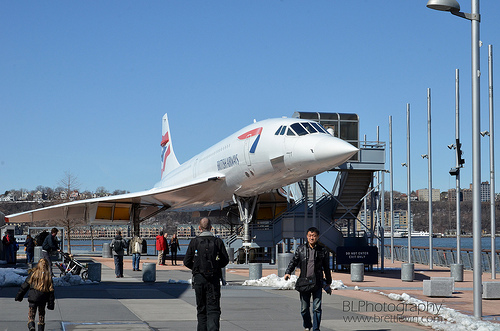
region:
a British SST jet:
[8, 93, 363, 234]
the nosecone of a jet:
[333, 135, 360, 162]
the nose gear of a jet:
[228, 202, 264, 272]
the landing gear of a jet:
[224, 190, 271, 258]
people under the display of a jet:
[13, 114, 358, 319]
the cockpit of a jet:
[278, 120, 329, 137]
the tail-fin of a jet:
[145, 108, 181, 163]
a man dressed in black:
[176, 213, 238, 327]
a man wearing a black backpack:
[174, 210, 236, 330]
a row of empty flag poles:
[366, 96, 499, 316]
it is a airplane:
[0, 108, 357, 221]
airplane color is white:
[0, 93, 365, 223]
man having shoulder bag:
[287, 271, 329, 293]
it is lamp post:
[427, 1, 498, 326]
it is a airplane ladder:
[327, 160, 388, 226]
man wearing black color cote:
[185, 212, 227, 327]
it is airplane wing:
[4, 182, 211, 233]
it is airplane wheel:
[240, 236, 270, 263]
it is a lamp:
[424, 1, 473, 28]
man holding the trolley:
[43, 229, 110, 279]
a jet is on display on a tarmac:
[3, 98, 359, 283]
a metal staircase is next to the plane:
[285, 107, 387, 272]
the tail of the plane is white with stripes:
[146, 107, 191, 180]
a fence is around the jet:
[3, 224, 499, 292]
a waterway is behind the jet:
[16, 226, 499, 301]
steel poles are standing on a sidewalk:
[365, 48, 498, 325]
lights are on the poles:
[380, 121, 493, 171]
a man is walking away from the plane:
[278, 221, 340, 329]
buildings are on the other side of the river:
[1, 173, 496, 247]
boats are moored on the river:
[367, 224, 448, 242]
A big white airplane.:
[5, 112, 357, 263]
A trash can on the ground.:
[85, 260, 101, 283]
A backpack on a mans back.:
[112, 237, 122, 251]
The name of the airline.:
[212, 154, 238, 170]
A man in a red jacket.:
[153, 231, 165, 266]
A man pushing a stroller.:
[60, 251, 90, 281]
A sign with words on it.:
[337, 244, 379, 264]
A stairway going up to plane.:
[292, 172, 314, 214]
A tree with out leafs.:
[57, 168, 78, 196]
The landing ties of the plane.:
[237, 247, 254, 265]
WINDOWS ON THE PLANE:
[287, 120, 332, 133]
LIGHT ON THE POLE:
[423, 0, 477, 17]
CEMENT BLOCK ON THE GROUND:
[422, 279, 446, 293]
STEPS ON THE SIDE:
[338, 218, 380, 260]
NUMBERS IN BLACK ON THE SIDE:
[203, 149, 246, 175]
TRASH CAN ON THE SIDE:
[345, 259, 361, 281]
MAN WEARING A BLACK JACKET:
[301, 253, 308, 265]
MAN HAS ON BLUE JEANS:
[315, 302, 325, 317]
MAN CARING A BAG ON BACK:
[200, 240, 220, 272]